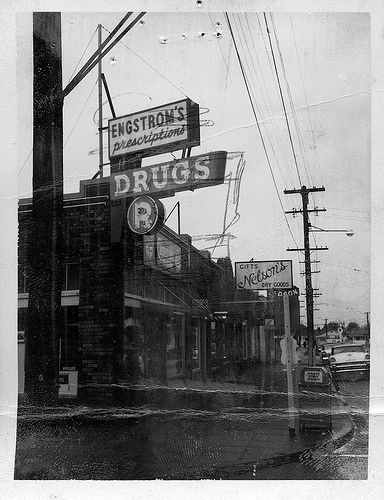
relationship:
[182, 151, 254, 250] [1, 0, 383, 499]
drawing on photograph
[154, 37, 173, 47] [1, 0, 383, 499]
hole in photograph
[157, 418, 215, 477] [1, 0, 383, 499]
fingerprint on photograph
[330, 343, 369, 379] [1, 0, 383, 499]
car in photograph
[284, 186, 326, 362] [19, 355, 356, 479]
pole on sidewalk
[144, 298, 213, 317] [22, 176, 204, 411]
awning on building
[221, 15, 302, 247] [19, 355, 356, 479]
wire above sidewalk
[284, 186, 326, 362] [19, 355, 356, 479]
pole along sidewalk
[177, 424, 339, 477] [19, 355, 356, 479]
curb of sidewalk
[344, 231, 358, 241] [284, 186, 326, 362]
light attached to pole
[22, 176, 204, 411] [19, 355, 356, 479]
building along sidewalk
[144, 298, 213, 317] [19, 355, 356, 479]
awning over sidewalk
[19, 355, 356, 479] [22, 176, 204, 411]
sidewalk in front of building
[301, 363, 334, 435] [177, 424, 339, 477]
container near curb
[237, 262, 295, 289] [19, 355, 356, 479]
sign on sidewalk